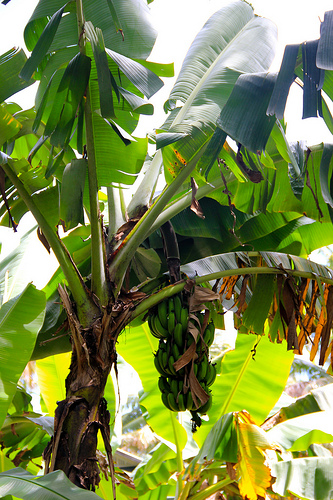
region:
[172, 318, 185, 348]
unripe banana in a bunch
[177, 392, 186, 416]
unripe banana in a bunch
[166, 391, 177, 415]
unripe banana in a bunch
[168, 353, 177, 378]
unripe banana in a bunch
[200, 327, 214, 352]
unripe banana in a bunch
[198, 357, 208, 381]
unripe banana in a bunch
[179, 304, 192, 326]
unripe banana in a bunch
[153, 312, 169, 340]
unripe banana in a bunch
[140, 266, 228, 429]
bunch of unripe bananas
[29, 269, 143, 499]
trunk of a banana tree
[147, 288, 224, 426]
bananas hanging on a tree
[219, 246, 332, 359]
brown banana tree leaves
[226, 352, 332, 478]
sun filtering in through the leaves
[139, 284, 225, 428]
cluster of bananas ripening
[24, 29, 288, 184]
canopy of banana tree leaves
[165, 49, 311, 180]
large green leaves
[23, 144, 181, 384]
green banana tree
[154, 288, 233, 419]
bananas ready for harvesting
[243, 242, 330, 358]
leaves drying out in the sun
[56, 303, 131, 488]
thick banana tree trunk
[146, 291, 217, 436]
banana bundle in tree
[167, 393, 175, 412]
banana hanging from tree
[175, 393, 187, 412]
banana hanging from tree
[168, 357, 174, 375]
banana hanging from tree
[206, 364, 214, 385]
banana hanging from tree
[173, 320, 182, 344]
banana hanging from tree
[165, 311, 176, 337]
banana hanging from tree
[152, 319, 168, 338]
banana hanging from tree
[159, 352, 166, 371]
banana hanging from tree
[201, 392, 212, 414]
banana hanging from tree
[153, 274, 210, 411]
banana bunch in tree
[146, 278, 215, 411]
green bananas on tree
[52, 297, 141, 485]
brown banana tree trunk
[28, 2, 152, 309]
green leaf on tree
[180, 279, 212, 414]
brown palm leaf on tree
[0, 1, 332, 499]
green and brown banana tree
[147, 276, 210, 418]
bananas in bunch on tree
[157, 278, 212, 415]
unripe bananas on tree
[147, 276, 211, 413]
bananas growing on palm tree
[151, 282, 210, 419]
bananas ripening on tree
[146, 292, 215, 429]
a bunch of green bananas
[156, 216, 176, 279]
a banana stock on the banana tree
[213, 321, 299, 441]
sunlight shining through the banana leaf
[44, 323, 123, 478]
the banana tree stem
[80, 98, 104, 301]
the banana tree branch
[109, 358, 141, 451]
sunlight shining through the leaves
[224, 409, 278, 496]
dried up banana leaf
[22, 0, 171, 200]
wind blown banana leaf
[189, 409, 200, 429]
the flowering end of the banana stock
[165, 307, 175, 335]
a green banana on the stock